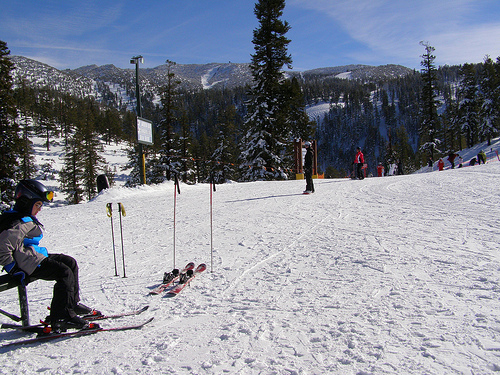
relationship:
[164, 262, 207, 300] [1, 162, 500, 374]
ski on slope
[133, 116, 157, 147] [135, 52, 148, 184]
sigh on post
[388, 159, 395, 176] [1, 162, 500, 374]
skier down slope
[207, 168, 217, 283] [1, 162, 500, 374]
pole in slope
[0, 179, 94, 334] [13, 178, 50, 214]
boy has a helmet